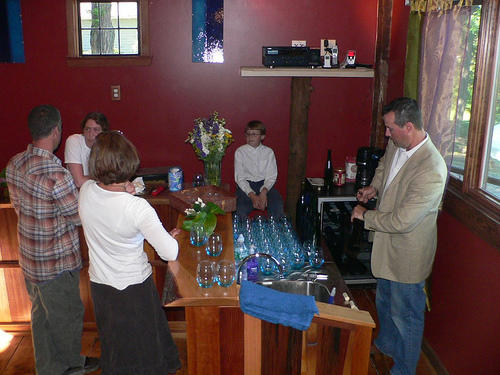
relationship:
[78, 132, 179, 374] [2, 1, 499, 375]
woman in room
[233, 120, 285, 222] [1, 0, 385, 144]
boy leaning on wall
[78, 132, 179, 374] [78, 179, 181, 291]
woman in shirt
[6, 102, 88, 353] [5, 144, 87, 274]
man in shirt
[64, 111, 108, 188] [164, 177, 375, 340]
woman near bar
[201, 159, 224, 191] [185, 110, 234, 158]
vase with flowers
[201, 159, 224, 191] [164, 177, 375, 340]
vase on bar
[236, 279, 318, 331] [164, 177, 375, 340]
cloth on bar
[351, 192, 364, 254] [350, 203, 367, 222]
bottle in hand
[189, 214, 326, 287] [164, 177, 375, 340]
glasses on bar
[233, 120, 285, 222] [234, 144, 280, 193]
boy in shirt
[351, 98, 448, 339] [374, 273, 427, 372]
man in pants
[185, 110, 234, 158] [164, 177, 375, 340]
flowers on bar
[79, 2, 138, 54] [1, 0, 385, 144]
window in wall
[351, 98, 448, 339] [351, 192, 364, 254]
man with bottle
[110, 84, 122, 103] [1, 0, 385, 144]
outlet on wall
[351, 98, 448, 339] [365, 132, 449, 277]
man in coat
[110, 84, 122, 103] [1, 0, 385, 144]
outlet in wall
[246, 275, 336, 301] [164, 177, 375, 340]
sink on bar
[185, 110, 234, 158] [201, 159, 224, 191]
flowers in vase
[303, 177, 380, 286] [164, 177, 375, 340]
fridge behind bar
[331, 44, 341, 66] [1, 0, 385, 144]
phone near wall